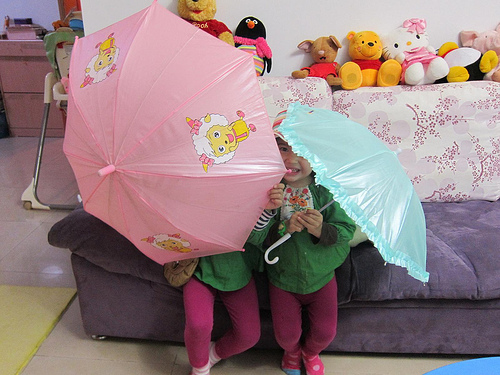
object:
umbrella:
[61, 1, 291, 266]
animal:
[174, 0, 235, 48]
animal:
[229, 16, 273, 76]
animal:
[290, 33, 344, 86]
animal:
[337, 30, 401, 90]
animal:
[378, 16, 450, 86]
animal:
[430, 42, 499, 85]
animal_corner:
[458, 22, 500, 81]